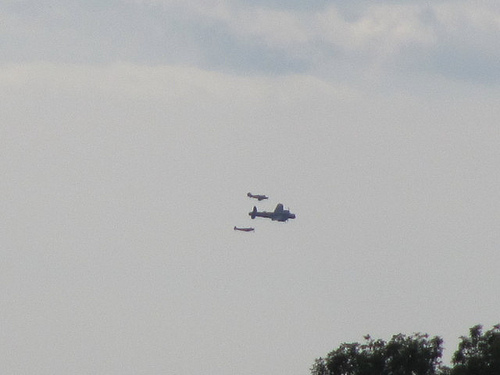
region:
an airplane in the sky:
[245, 199, 301, 224]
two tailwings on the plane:
[245, 199, 261, 225]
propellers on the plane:
[279, 205, 294, 225]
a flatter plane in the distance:
[230, 223, 255, 235]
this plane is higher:
[237, 187, 270, 204]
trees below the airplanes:
[304, 312, 494, 372]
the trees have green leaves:
[295, 322, 498, 369]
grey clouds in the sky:
[4, 2, 498, 372]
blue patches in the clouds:
[151, 17, 488, 86]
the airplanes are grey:
[214, 177, 307, 254]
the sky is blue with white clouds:
[22, 16, 492, 364]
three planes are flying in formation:
[218, 185, 305, 247]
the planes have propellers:
[225, 183, 301, 244]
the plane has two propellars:
[271, 202, 300, 230]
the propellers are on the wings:
[248, 200, 300, 225]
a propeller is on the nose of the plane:
[229, 220, 259, 242]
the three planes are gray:
[223, 186, 299, 235]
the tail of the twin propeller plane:
[243, 205, 263, 222]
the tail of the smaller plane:
[229, 223, 240, 234]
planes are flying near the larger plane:
[226, 180, 299, 237]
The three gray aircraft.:
[229, 187, 306, 237]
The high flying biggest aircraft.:
[245, 203, 305, 223]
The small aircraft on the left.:
[227, 224, 256, 236]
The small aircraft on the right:
[241, 189, 272, 202]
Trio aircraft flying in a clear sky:
[231, 187, 301, 237]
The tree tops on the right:
[319, 324, 499, 374]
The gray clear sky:
[0, 0, 498, 373]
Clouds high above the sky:
[0, 0, 497, 136]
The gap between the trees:
[431, 333, 463, 373]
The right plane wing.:
[272, 202, 287, 217]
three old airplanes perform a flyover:
[228, 187, 302, 237]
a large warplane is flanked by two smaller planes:
[227, 188, 299, 236]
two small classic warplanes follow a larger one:
[230, 187, 301, 235]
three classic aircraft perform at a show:
[228, 188, 301, 238]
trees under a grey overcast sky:
[304, 312, 499, 373]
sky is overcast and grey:
[3, 5, 494, 372]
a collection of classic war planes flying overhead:
[227, 185, 297, 235]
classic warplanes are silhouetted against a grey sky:
[225, 185, 300, 231]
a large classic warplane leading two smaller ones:
[227, 188, 297, 234]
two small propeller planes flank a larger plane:
[226, 187, 300, 239]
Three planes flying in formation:
[218, 174, 313, 256]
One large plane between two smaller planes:
[230, 180, 303, 245]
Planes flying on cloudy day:
[106, 38, 322, 273]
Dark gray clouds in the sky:
[171, 37, 448, 112]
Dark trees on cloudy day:
[286, 299, 492, 372]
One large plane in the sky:
[243, 202, 302, 230]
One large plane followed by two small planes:
[203, 187, 308, 261]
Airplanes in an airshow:
[204, 173, 313, 238]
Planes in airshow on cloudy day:
[78, 42, 342, 290]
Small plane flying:
[219, 169, 272, 204]